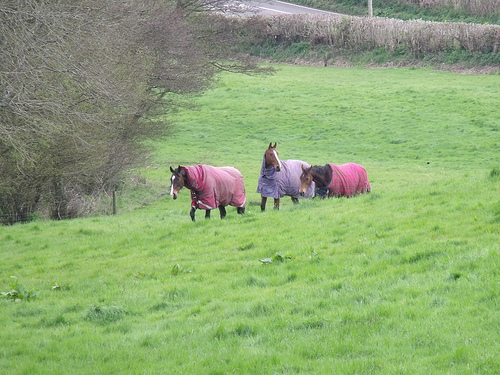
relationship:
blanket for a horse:
[187, 165, 248, 209] [162, 162, 246, 221]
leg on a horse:
[184, 198, 201, 220] [164, 160, 250, 217]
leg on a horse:
[202, 202, 213, 222] [164, 160, 250, 217]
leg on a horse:
[214, 200, 228, 221] [164, 160, 250, 217]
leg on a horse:
[255, 195, 269, 215] [164, 160, 250, 217]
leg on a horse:
[271, 194, 283, 214] [252, 136, 322, 213]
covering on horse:
[262, 160, 312, 200] [260, 143, 310, 210]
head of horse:
[170, 165, 187, 200] [167, 159, 251, 223]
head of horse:
[264, 142, 280, 171] [256, 142, 317, 210]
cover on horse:
[333, 165, 369, 192] [298, 166, 370, 193]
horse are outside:
[169, 164, 247, 222] [3, 4, 498, 371]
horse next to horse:
[169, 164, 247, 222] [252, 136, 322, 213]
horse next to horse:
[169, 164, 247, 222] [293, 155, 377, 201]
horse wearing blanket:
[164, 166, 275, 244] [196, 147, 256, 211]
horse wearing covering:
[259, 144, 319, 211] [256, 153, 315, 200]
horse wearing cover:
[297, 160, 376, 197] [326, 163, 370, 197]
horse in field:
[169, 164, 247, 222] [27, 55, 497, 370]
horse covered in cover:
[299, 163, 370, 198] [326, 163, 370, 197]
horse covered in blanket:
[169, 164, 247, 222] [186, 165, 245, 210]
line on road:
[228, 0, 297, 18] [185, 4, 495, 58]